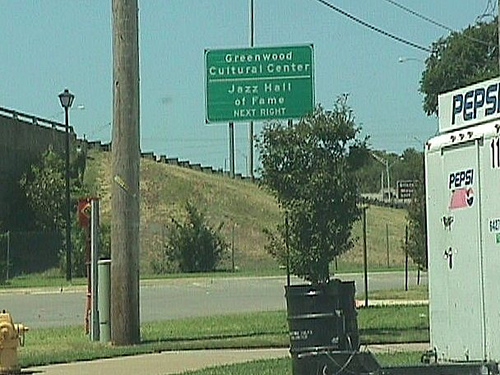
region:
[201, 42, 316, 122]
A directional sign above the road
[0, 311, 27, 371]
A hydrant on the sidewalk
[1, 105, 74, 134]
A railing by the side of the road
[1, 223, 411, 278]
A fence by the hill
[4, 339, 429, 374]
The sidewalk by the street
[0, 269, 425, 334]
The street below the green sign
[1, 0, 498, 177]
The sky above the road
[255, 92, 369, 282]
A small tree by the sidewalk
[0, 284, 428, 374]
Grass next to the sidewalk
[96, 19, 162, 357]
a brown wooden post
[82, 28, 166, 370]
a brown wooden post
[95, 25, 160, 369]
a brown wooden post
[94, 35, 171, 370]
a brown wooden post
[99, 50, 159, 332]
a brown wooden post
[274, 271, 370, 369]
the bin is black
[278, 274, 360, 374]
the bin is black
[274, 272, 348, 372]
the bin is black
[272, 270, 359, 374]
the bin is black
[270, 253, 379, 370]
the bin is black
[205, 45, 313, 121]
a large green street sign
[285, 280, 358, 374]
a black trash can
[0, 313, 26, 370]
a yellow fire hydrant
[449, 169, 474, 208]
a beverage logo on the door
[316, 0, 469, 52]
two electrical lines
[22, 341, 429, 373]
a concrete sidewalk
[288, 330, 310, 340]
white lettering on the can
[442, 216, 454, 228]
metal door handle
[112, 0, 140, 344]
a wooden electrical post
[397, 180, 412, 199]
a black street sign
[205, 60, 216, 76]
The letter is white.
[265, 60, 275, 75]
The letter is white.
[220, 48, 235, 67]
The letter is white.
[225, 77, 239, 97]
The letter is white.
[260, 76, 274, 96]
The letter is white.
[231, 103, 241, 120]
The letter is white.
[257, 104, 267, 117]
The letter is white.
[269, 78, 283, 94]
The letter is white.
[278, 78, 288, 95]
The letter is white.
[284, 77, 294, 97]
The letter is white.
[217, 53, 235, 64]
alphabet on a plate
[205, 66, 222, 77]
alphabet on a plate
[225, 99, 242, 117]
alphabet on a plate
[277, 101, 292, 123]
alphabet on a plate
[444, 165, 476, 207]
logo is on side of trailer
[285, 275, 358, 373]
black garbage can next to trailer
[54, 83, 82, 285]
street lamp next to street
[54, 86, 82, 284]
street lamp is turned off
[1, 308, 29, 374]
fire hydrant is painted yellow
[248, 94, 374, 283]
tree is near street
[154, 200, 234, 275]
bush is near street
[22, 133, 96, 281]
tree is near street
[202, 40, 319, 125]
rectangular sign is green and white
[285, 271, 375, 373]
a black metal barrel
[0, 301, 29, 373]
a yellow fire hydrant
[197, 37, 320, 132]
a green and white street sign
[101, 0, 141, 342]
a wood electrical pole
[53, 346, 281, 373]
a concrete sidewalk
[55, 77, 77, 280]
a tall black street light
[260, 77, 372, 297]
a small tree next to a street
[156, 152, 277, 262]
a hillside covered with grass